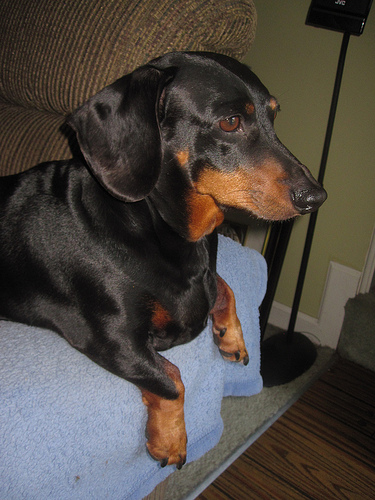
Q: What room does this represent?
A: It represents the living room.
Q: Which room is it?
A: It is a living room.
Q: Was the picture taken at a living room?
A: Yes, it was taken in a living room.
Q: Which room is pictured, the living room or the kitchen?
A: It is the living room.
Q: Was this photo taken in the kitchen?
A: No, the picture was taken in the living room.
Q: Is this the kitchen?
A: No, it is the living room.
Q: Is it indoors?
A: Yes, it is indoors.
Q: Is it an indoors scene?
A: Yes, it is indoors.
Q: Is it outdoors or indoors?
A: It is indoors.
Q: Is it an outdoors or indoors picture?
A: It is indoors.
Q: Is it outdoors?
A: No, it is indoors.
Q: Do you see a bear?
A: No, there are no bears.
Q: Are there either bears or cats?
A: No, there are no bears or cats.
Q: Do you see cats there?
A: No, there are no cats.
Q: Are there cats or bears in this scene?
A: No, there are no cats or bears.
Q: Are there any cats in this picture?
A: No, there are no cats.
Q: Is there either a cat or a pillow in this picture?
A: No, there are no cats or pillows.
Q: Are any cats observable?
A: No, there are no cats.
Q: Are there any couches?
A: Yes, there is a couch.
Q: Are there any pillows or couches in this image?
A: Yes, there is a couch.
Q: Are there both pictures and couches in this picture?
A: No, there is a couch but no pictures.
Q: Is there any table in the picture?
A: No, there are no tables.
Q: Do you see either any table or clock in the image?
A: No, there are no tables or clocks.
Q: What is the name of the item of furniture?
A: The piece of furniture is a couch.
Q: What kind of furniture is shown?
A: The furniture is a couch.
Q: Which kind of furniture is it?
A: The piece of furniture is a couch.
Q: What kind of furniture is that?
A: This is a couch.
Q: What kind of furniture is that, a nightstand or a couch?
A: This is a couch.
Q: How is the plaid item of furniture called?
A: The piece of furniture is a couch.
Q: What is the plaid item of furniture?
A: The piece of furniture is a couch.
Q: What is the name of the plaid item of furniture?
A: The piece of furniture is a couch.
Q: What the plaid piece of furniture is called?
A: The piece of furniture is a couch.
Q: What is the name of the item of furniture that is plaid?
A: The piece of furniture is a couch.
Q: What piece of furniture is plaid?
A: The piece of furniture is a couch.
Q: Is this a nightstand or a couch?
A: This is a couch.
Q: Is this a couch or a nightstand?
A: This is a couch.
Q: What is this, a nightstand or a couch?
A: This is a couch.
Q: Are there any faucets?
A: No, there are no faucets.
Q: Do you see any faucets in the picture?
A: No, there are no faucets.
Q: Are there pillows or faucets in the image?
A: No, there are no faucets or pillows.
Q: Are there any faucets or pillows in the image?
A: No, there are no faucets or pillows.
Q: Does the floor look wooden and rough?
A: No, the floor is wooden but smooth.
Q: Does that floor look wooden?
A: Yes, the floor is wooden.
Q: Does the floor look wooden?
A: Yes, the floor is wooden.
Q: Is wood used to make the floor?
A: Yes, the floor is made of wood.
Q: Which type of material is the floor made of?
A: The floor is made of wood.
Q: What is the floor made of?
A: The floor is made of wood.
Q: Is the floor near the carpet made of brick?
A: No, the floor is made of wood.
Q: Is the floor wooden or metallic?
A: The floor is wooden.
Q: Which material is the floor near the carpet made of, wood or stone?
A: The floor is made of wood.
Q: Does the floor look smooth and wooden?
A: Yes, the floor is smooth and wooden.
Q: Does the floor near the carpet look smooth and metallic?
A: No, the floor is smooth but wooden.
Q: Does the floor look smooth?
A: Yes, the floor is smooth.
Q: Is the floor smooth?
A: Yes, the floor is smooth.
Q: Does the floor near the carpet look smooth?
A: Yes, the floor is smooth.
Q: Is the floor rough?
A: No, the floor is smooth.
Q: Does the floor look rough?
A: No, the floor is smooth.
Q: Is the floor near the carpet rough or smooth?
A: The floor is smooth.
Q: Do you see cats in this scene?
A: No, there are no cats.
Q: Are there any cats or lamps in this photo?
A: No, there are no cats or lamps.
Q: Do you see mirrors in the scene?
A: No, there are no mirrors.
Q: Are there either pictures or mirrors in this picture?
A: No, there are no mirrors or pictures.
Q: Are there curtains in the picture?
A: No, there are no curtains.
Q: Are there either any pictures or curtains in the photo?
A: No, there are no curtains or pictures.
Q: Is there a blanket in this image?
A: Yes, there is a blanket.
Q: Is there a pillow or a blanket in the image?
A: Yes, there is a blanket.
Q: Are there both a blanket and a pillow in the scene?
A: No, there is a blanket but no pillows.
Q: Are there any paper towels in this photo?
A: No, there are no paper towels.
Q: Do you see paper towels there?
A: No, there are no paper towels.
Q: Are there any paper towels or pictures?
A: No, there are no paper towels or pictures.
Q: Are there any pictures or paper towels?
A: No, there are no paper towels or pictures.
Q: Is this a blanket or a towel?
A: This is a blanket.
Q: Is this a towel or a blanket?
A: This is a blanket.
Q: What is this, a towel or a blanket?
A: This is a blanket.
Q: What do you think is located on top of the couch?
A: The blanket is on top of the couch.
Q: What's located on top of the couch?
A: The blanket is on top of the couch.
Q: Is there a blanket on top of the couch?
A: Yes, there is a blanket on top of the couch.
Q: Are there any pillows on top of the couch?
A: No, there is a blanket on top of the couch.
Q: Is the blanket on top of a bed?
A: No, the blanket is on top of the couch.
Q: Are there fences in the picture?
A: No, there are no fences.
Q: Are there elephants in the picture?
A: No, there are no elephants.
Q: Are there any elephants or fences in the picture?
A: No, there are no elephants or fences.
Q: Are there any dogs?
A: Yes, there is a dog.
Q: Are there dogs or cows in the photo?
A: Yes, there is a dog.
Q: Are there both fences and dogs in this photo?
A: No, there is a dog but no fences.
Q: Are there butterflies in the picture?
A: No, there are no butterflies.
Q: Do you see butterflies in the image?
A: No, there are no butterflies.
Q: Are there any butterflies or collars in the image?
A: No, there are no butterflies or collars.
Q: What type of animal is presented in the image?
A: The animal is a dog.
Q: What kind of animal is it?
A: The animal is a dog.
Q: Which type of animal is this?
A: This is a dog.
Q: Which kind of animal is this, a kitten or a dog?
A: This is a dog.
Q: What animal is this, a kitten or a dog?
A: This is a dog.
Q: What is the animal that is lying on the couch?
A: The animal is a dog.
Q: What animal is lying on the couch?
A: The animal is a dog.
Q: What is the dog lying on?
A: The dog is lying on the couch.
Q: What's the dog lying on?
A: The dog is lying on the couch.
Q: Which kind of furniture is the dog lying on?
A: The dog is lying on the couch.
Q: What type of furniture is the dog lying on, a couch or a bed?
A: The dog is lying on a couch.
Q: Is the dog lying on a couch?
A: Yes, the dog is lying on a couch.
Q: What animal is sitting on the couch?
A: The dog is sitting on the couch.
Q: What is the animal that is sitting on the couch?
A: The animal is a dog.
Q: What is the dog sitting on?
A: The dog is sitting on the couch.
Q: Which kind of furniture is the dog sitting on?
A: The dog is sitting on the couch.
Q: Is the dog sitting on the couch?
A: Yes, the dog is sitting on the couch.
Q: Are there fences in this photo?
A: No, there are no fences.